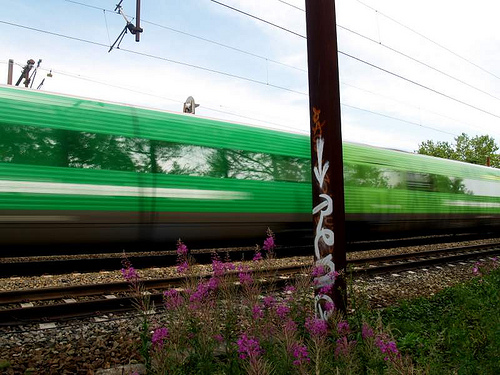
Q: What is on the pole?
A: An arrow with the word Reno.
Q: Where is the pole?
A: Near a railroad.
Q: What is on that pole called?
A: Graffitti.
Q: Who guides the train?
A: An engineer.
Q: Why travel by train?
A: Cheap and fast.